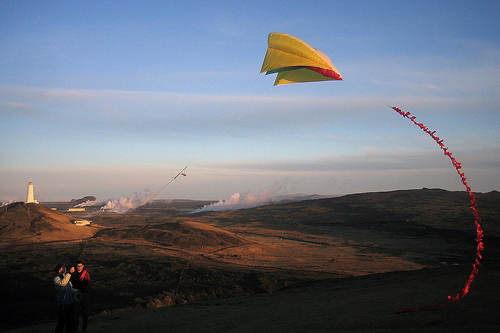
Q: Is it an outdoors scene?
A: Yes, it is outdoors.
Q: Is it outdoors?
A: Yes, it is outdoors.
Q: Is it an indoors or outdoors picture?
A: It is outdoors.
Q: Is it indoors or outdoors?
A: It is outdoors.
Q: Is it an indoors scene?
A: No, it is outdoors.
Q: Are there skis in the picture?
A: No, there are no skis.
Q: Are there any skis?
A: No, there are no skis.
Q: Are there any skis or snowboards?
A: No, there are no skis or snowboards.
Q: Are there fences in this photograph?
A: No, there are no fences.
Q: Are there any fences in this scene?
A: No, there are no fences.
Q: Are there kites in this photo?
A: Yes, there is a kite.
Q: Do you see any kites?
A: Yes, there is a kite.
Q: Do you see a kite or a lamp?
A: Yes, there is a kite.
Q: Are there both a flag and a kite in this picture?
A: No, there is a kite but no flags.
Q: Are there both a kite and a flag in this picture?
A: No, there is a kite but no flags.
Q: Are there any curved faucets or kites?
A: Yes, there is a curved kite.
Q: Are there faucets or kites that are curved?
A: Yes, the kite is curved.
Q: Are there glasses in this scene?
A: No, there are no glasses.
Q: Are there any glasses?
A: No, there are no glasses.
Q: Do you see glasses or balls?
A: No, there are no glasses or balls.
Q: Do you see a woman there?
A: No, there are no women.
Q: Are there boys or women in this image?
A: No, there are no women or boys.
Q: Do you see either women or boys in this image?
A: No, there are no women or boys.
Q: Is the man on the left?
A: Yes, the man is on the left of the image.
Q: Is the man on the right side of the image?
A: No, the man is on the left of the image.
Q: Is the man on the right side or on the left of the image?
A: The man is on the left of the image.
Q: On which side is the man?
A: The man is on the left of the image.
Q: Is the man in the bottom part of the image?
A: Yes, the man is in the bottom of the image.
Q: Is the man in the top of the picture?
A: No, the man is in the bottom of the image.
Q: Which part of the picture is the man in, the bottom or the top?
A: The man is in the bottom of the image.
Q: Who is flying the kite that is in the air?
A: The man is flying the kite.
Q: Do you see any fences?
A: No, there are no fences.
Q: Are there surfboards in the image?
A: No, there are no surfboards.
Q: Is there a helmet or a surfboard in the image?
A: No, there are no surfboards or helmets.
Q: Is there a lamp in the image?
A: No, there are no lamps.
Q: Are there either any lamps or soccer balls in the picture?
A: No, there are no lamps or soccer balls.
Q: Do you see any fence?
A: No, there are no fences.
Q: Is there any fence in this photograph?
A: No, there are no fences.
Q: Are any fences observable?
A: No, there are no fences.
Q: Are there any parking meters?
A: No, there are no parking meters.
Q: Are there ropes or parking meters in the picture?
A: No, there are no parking meters or ropes.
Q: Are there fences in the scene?
A: No, there are no fences.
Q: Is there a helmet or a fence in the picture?
A: No, there are no fences or helmets.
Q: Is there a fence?
A: No, there are no fences.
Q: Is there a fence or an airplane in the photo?
A: No, there are no fences or airplanes.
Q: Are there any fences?
A: No, there are no fences.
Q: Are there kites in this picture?
A: Yes, there is a kite.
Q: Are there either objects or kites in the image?
A: Yes, there is a kite.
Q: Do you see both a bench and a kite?
A: No, there is a kite but no benches.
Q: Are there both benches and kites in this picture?
A: No, there is a kite but no benches.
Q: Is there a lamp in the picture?
A: No, there are no lamps.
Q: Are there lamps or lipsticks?
A: No, there are no lamps or lipsticks.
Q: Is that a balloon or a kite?
A: That is a kite.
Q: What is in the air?
A: The kite is in the air.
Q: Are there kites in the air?
A: Yes, there is a kite in the air.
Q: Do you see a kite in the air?
A: Yes, there is a kite in the air.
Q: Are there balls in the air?
A: No, there is a kite in the air.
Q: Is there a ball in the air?
A: No, there is a kite in the air.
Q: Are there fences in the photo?
A: No, there are no fences.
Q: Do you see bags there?
A: No, there are no bags.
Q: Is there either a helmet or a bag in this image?
A: No, there are no bags or helmets.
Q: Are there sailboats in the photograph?
A: No, there are no sailboats.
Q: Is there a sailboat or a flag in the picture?
A: No, there are no sailboats or flags.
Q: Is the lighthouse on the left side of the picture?
A: Yes, the lighthouse is on the left of the image.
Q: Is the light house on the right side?
A: No, the light house is on the left of the image.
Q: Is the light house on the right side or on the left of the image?
A: The light house is on the left of the image.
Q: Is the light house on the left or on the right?
A: The light house is on the left of the image.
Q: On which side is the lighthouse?
A: The lighthouse is on the left of the image.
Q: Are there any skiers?
A: No, there are no skiers.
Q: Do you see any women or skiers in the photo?
A: No, there are no skiers or women.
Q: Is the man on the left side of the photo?
A: Yes, the man is on the left of the image.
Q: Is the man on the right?
A: No, the man is on the left of the image.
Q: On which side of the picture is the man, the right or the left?
A: The man is on the left of the image.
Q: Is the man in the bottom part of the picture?
A: Yes, the man is in the bottom of the image.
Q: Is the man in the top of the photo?
A: No, the man is in the bottom of the image.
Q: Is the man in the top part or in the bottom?
A: The man is in the bottom of the image.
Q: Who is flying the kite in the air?
A: The man is flying the kite.